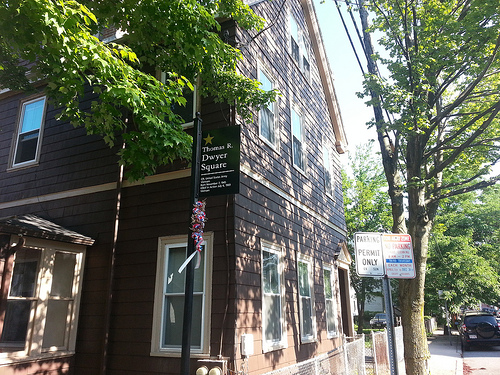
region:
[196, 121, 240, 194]
Sign attached to utility pole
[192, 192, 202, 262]
Bouquet of flowers attached to utility pole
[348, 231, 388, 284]
Permit parking only sign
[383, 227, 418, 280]
No parking sign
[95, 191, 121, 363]
Down pipe of a gutter on a house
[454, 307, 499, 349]
SUV parked in the parking lot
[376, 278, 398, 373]
Post for street signs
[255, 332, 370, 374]
Chain-link security fence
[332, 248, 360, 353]
Access door to a building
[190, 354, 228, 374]
Electric meter attached to side of the house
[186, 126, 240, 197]
Gold star on black sign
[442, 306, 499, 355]
Black car parked along sidewalk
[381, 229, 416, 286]
Red, white and blue parking sign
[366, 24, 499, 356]
Tree's branches only growing on right side of tree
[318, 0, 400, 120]
Power lines above tree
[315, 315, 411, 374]
Chain link fence near brown house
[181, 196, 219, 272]
Red, white and blue decoration under sign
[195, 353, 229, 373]
Electric meter on front of house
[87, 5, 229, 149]
Tree branch covering window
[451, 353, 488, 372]
Pile of leaves next to sidewalk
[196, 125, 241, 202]
sign on metal pole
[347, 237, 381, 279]
sign on metal pole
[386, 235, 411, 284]
sign on metal pole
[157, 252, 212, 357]
window on side of house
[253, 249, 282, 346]
window on side of house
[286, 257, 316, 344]
window on side of house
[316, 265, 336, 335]
window on side of house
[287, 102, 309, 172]
window on side of house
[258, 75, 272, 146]
window on side of house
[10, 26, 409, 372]
three story brown building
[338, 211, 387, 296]
parking permit only sign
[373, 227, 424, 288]
no parking warning sign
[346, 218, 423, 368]
two street signs on pole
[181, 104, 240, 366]
street description sign on pole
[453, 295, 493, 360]
vehicle parked on curb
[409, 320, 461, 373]
sidewalk beside brown building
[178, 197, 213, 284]
red, white, and blue ribbon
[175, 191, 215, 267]
ribbon tied to pole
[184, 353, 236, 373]
electrical meters on building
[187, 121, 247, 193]
A black sign with white writing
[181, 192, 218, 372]
Metal pole holding up the sign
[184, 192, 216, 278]
A ribbon hanging on the pole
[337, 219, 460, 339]
Two signs on one pole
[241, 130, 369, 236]
Wooden siding on building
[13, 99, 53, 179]
Window on the upstairs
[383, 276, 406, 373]
Metal pole holding up signs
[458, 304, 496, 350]
Car parked near sidewalk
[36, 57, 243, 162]
Tree limb touching the building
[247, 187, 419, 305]
Shadow from leaves on building